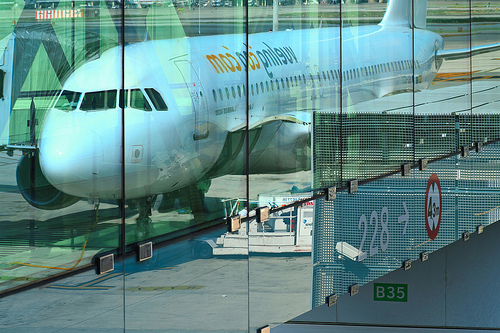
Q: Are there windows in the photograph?
A: Yes, there are windows.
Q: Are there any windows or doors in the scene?
A: Yes, there are windows.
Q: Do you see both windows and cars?
A: No, there are windows but no cars.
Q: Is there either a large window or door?
A: Yes, there are large windows.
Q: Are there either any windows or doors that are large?
A: Yes, the windows are large.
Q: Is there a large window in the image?
A: Yes, there are large windows.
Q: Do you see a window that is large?
A: Yes, there are windows that are large.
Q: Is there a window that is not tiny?
A: Yes, there are large windows.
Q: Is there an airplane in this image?
A: Yes, there is an airplane.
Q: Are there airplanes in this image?
A: Yes, there is an airplane.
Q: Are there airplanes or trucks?
A: Yes, there is an airplane.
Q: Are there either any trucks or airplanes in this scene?
A: Yes, there is an airplane.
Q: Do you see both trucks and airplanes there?
A: No, there is an airplane but no trucks.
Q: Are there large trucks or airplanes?
A: Yes, there is a large airplane.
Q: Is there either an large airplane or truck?
A: Yes, there is a large airplane.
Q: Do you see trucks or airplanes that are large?
A: Yes, the airplane is large.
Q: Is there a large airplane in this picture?
A: Yes, there is a large airplane.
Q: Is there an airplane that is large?
A: Yes, there is an airplane that is large.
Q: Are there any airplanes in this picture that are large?
A: Yes, there is an airplane that is large.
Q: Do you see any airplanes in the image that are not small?
A: Yes, there is a large airplane.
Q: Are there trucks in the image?
A: No, there are no trucks.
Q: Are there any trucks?
A: No, there are no trucks.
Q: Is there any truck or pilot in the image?
A: No, there are no trucks or pilots.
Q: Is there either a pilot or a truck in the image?
A: No, there are no trucks or pilots.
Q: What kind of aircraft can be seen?
A: The aircraft is an airplane.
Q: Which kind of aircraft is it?
A: The aircraft is an airplane.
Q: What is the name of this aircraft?
A: This is an airplane.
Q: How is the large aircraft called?
A: The aircraft is an airplane.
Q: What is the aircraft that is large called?
A: The aircraft is an airplane.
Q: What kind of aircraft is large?
A: The aircraft is an airplane.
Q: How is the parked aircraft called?
A: The aircraft is an airplane.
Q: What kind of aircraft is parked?
A: The aircraft is an airplane.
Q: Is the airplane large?
A: Yes, the airplane is large.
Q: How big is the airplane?
A: The airplane is large.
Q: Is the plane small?
A: No, the plane is large.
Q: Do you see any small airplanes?
A: No, there is an airplane but it is large.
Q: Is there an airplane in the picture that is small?
A: No, there is an airplane but it is large.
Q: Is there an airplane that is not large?
A: No, there is an airplane but it is large.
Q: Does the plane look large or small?
A: The plane is large.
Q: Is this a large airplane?
A: Yes, this is a large airplane.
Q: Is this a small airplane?
A: No, this is a large airplane.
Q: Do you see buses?
A: No, there are no buses.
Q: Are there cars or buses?
A: No, there are no buses or cars.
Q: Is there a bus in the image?
A: No, there are no buses.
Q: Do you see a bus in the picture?
A: No, there are no buses.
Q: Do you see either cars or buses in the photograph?
A: No, there are no buses or cars.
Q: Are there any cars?
A: No, there are no cars.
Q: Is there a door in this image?
A: Yes, there is a door.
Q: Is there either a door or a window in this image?
A: Yes, there is a door.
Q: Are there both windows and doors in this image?
A: Yes, there are both a door and a window.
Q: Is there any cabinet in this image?
A: No, there are no cabinets.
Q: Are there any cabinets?
A: No, there are no cabinets.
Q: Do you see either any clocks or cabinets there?
A: No, there are no cabinets or clocks.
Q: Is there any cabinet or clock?
A: No, there are no cabinets or clocks.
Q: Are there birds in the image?
A: No, there are no birds.